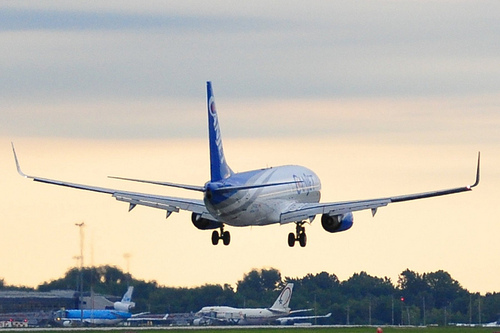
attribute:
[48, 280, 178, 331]
plane — blue, white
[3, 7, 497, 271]
clouds — white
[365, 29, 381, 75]
clouds — white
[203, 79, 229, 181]
tail — blue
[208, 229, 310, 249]
wheels — black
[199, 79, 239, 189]
tail — blue, white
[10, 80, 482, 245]
plane — large, metal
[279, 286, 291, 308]
circle — red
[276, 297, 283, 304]
star — blue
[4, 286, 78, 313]
airport — large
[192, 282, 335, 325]
airplanes — blue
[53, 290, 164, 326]
airplanes — silver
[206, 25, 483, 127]
sky — cloudy, unique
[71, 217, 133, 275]
towers — tall, far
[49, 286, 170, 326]
plane — parked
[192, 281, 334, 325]
plane — parked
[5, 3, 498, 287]
sky — blue